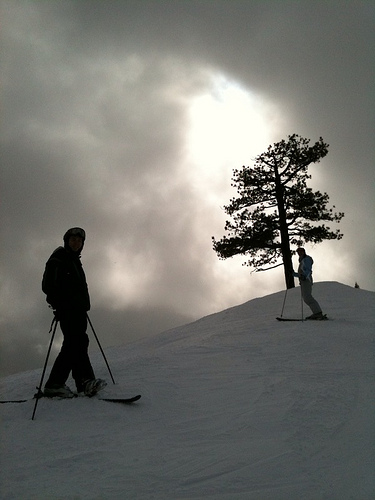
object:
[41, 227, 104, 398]
skier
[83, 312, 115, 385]
ski pole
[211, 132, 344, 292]
tree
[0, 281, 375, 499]
mountain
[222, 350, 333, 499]
snow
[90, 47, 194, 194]
clouds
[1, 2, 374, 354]
sky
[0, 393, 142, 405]
skis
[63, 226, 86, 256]
head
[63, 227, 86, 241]
helmet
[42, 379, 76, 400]
boots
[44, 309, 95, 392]
pants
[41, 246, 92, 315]
jacket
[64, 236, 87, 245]
goggles